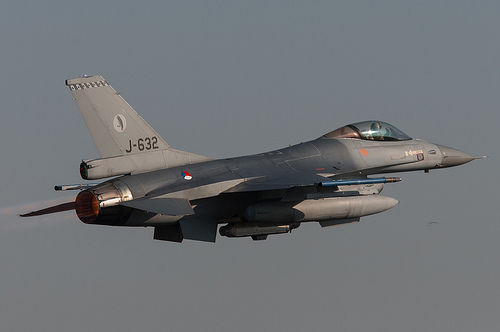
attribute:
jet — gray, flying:
[18, 74, 490, 245]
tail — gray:
[63, 72, 213, 173]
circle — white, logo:
[112, 113, 131, 133]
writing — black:
[126, 135, 165, 155]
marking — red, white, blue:
[180, 169, 195, 181]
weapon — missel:
[314, 175, 405, 187]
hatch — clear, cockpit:
[350, 119, 416, 143]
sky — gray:
[2, 2, 499, 328]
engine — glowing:
[74, 178, 134, 229]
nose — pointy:
[435, 144, 489, 167]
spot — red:
[359, 145, 373, 157]